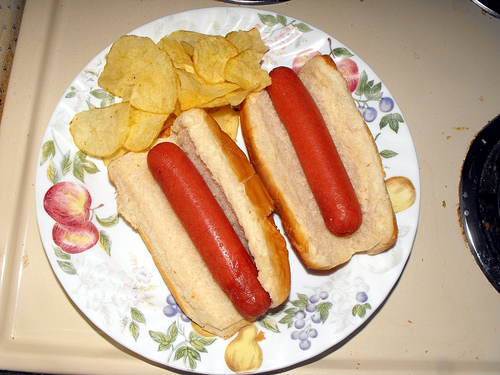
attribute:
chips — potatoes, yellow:
[69, 26, 271, 167]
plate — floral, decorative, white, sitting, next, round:
[34, 8, 421, 373]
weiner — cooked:
[147, 138, 276, 322]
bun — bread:
[239, 53, 400, 274]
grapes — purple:
[286, 287, 330, 351]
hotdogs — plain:
[109, 54, 402, 337]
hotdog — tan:
[263, 62, 362, 236]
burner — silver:
[466, 104, 500, 297]